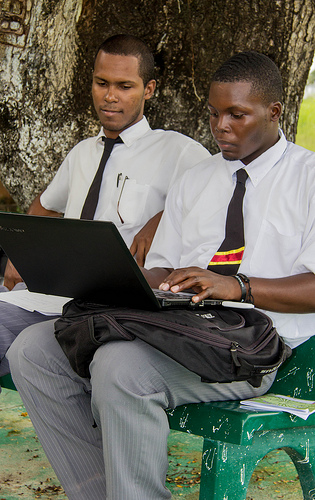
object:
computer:
[0, 211, 255, 311]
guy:
[3, 48, 313, 500]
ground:
[0, 389, 315, 500]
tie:
[205, 162, 248, 275]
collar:
[225, 128, 288, 187]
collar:
[95, 114, 151, 149]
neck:
[241, 137, 280, 165]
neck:
[100, 123, 134, 139]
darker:
[225, 208, 243, 244]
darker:
[80, 191, 99, 220]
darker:
[92, 284, 143, 306]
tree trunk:
[0, 0, 315, 211]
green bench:
[0, 340, 315, 500]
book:
[240, 393, 314, 421]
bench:
[0, 297, 63, 376]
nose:
[104, 84, 119, 104]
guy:
[0, 34, 212, 405]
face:
[91, 51, 144, 131]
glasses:
[116, 175, 129, 224]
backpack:
[54, 289, 292, 387]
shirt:
[142, 126, 314, 338]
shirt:
[0, 115, 213, 317]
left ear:
[270, 99, 282, 122]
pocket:
[109, 176, 147, 231]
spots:
[213, 414, 226, 433]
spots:
[179, 413, 190, 430]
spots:
[201, 444, 218, 469]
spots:
[239, 464, 246, 487]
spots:
[247, 428, 255, 441]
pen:
[116, 172, 123, 187]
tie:
[78, 134, 120, 221]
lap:
[52, 299, 291, 389]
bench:
[4, 316, 279, 500]